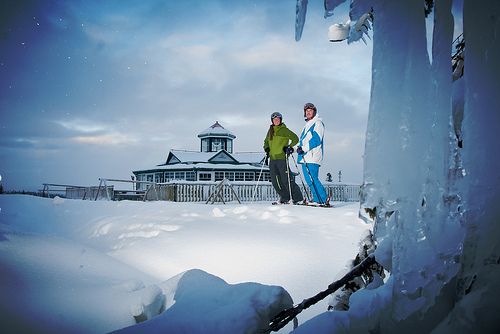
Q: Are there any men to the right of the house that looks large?
A: Yes, there is a man to the right of the house.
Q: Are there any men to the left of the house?
A: No, the man is to the right of the house.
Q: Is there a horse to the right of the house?
A: No, there is a man to the right of the house.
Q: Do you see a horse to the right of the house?
A: No, there is a man to the right of the house.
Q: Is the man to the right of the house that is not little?
A: Yes, the man is to the right of the house.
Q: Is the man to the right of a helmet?
A: No, the man is to the right of the house.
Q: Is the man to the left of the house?
A: No, the man is to the right of the house.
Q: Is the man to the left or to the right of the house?
A: The man is to the right of the house.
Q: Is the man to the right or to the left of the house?
A: The man is to the right of the house.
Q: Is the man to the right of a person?
A: Yes, the man is to the right of a person.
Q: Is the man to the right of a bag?
A: No, the man is to the right of a person.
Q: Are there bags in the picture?
A: No, there are no bags.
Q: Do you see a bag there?
A: No, there are no bags.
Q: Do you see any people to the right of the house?
A: Yes, there is a person to the right of the house.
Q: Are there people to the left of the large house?
A: No, the person is to the right of the house.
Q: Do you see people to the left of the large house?
A: No, the person is to the right of the house.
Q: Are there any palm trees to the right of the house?
A: No, there is a person to the right of the house.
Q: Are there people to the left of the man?
A: Yes, there is a person to the left of the man.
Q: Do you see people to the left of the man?
A: Yes, there is a person to the left of the man.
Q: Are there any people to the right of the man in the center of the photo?
A: No, the person is to the left of the man.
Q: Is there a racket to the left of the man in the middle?
A: No, there is a person to the left of the man.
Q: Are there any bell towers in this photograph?
A: No, there are no bell towers.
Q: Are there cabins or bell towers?
A: No, there are no bell towers or cabins.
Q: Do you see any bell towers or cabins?
A: No, there are no bell towers or cabins.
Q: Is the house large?
A: Yes, the house is large.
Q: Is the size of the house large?
A: Yes, the house is large.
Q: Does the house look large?
A: Yes, the house is large.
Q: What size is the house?
A: The house is large.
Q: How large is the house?
A: The house is large.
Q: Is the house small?
A: No, the house is large.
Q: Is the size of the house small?
A: No, the house is large.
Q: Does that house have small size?
A: No, the house is large.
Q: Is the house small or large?
A: The house is large.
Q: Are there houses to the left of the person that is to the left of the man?
A: Yes, there is a house to the left of the person.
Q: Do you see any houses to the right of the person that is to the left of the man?
A: No, the house is to the left of the person.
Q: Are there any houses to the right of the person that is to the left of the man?
A: No, the house is to the left of the person.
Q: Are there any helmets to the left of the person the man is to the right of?
A: No, there is a house to the left of the person.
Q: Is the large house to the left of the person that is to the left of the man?
A: Yes, the house is to the left of the person.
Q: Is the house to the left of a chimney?
A: No, the house is to the left of the person.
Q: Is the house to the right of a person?
A: No, the house is to the left of a person.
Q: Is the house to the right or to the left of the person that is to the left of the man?
A: The house is to the left of the person.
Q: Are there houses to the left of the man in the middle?
A: Yes, there is a house to the left of the man.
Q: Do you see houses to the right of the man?
A: No, the house is to the left of the man.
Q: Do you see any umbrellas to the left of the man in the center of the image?
A: No, there is a house to the left of the man.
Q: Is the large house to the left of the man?
A: Yes, the house is to the left of the man.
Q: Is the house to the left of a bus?
A: No, the house is to the left of the man.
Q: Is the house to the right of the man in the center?
A: No, the house is to the left of the man.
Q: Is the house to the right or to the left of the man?
A: The house is to the left of the man.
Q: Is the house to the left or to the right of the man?
A: The house is to the left of the man.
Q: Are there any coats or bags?
A: Yes, there is a coat.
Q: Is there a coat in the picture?
A: Yes, there is a coat.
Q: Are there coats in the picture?
A: Yes, there is a coat.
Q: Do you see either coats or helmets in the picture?
A: Yes, there is a coat.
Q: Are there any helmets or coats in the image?
A: Yes, there is a coat.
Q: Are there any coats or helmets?
A: Yes, there is a coat.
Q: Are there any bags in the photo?
A: No, there are no bags.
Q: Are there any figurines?
A: No, there are no figurines.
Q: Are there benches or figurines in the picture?
A: No, there are no figurines or benches.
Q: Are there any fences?
A: Yes, there is a fence.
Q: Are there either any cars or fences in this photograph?
A: Yes, there is a fence.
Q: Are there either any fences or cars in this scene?
A: Yes, there is a fence.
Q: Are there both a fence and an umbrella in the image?
A: No, there is a fence but no umbrellas.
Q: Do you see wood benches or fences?
A: Yes, there is a wood fence.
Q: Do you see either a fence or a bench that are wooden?
A: Yes, the fence is wooden.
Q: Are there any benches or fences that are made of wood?
A: Yes, the fence is made of wood.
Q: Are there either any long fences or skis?
A: Yes, there is a long fence.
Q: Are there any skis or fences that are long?
A: Yes, the fence is long.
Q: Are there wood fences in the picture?
A: Yes, there is a wood fence.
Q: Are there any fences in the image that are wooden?
A: Yes, there is a fence that is wooden.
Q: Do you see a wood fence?
A: Yes, there is a fence that is made of wood.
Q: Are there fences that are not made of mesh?
A: Yes, there is a fence that is made of wood.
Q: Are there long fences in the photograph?
A: Yes, there is a long fence.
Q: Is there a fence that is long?
A: Yes, there is a long fence.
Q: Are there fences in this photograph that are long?
A: Yes, there is a fence that is long.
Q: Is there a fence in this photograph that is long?
A: Yes, there is a fence that is long.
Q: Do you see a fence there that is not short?
A: Yes, there is a long fence.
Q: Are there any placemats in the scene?
A: No, there are no placemats.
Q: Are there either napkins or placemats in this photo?
A: No, there are no placemats or napkins.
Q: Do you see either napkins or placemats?
A: No, there are no placemats or napkins.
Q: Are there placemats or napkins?
A: No, there are no placemats or napkins.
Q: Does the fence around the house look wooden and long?
A: Yes, the fence is wooden and long.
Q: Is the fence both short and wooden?
A: No, the fence is wooden but long.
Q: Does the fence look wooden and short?
A: No, the fence is wooden but long.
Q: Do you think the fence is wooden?
A: Yes, the fence is wooden.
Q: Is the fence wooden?
A: Yes, the fence is wooden.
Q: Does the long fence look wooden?
A: Yes, the fence is wooden.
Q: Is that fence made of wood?
A: Yes, the fence is made of wood.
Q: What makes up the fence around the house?
A: The fence is made of wood.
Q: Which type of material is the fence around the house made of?
A: The fence is made of wood.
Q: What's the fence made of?
A: The fence is made of wood.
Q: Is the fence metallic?
A: No, the fence is wooden.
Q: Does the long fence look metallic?
A: No, the fence is wooden.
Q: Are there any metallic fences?
A: No, there is a fence but it is wooden.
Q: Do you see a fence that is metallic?
A: No, there is a fence but it is wooden.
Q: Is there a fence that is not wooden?
A: No, there is a fence but it is wooden.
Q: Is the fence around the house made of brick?
A: No, the fence is made of wood.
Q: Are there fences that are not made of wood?
A: No, there is a fence but it is made of wood.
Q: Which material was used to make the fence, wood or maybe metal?
A: The fence is made of wood.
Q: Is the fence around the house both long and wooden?
A: Yes, the fence is long and wooden.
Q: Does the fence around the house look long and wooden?
A: Yes, the fence is long and wooden.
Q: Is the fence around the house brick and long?
A: No, the fence is long but wooden.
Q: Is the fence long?
A: Yes, the fence is long.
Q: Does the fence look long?
A: Yes, the fence is long.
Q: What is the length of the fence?
A: The fence is long.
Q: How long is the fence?
A: The fence is long.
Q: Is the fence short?
A: No, the fence is long.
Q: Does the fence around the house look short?
A: No, the fence is long.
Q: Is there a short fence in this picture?
A: No, there is a fence but it is long.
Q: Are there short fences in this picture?
A: No, there is a fence but it is long.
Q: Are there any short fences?
A: No, there is a fence but it is long.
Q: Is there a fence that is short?
A: No, there is a fence but it is long.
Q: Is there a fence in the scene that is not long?
A: No, there is a fence but it is long.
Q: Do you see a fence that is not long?
A: No, there is a fence but it is long.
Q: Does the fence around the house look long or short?
A: The fence is long.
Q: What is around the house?
A: The fence is around the house.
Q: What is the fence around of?
A: The fence is around the house.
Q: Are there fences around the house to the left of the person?
A: Yes, there is a fence around the house.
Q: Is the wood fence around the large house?
A: Yes, the fence is around the house.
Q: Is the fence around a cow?
A: No, the fence is around the house.